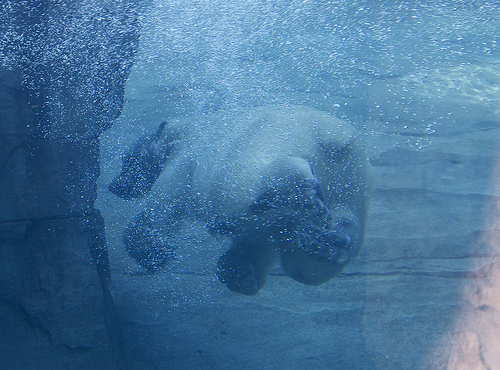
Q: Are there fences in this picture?
A: No, there are no fences.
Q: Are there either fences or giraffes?
A: No, there are no fences or giraffes.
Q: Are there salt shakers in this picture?
A: No, there are no salt shakers.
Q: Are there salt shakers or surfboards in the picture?
A: No, there are no salt shakers or surfboards.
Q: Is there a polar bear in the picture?
A: Yes, there is a polar bear.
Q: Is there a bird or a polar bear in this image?
A: Yes, there is a polar bear.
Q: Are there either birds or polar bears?
A: Yes, there is a polar bear.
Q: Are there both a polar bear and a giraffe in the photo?
A: No, there is a polar bear but no giraffes.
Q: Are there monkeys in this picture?
A: No, there are no monkeys.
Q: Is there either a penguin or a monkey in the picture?
A: No, there are no monkeys or penguins.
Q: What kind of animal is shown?
A: The animal is a polar bear.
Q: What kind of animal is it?
A: The animal is a polar bear.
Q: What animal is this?
A: That is a polar bear.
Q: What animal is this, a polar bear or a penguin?
A: That is a polar bear.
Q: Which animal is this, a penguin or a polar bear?
A: That is a polar bear.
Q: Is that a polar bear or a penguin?
A: That is a polar bear.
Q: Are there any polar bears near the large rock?
A: Yes, there is a polar bear near the rock.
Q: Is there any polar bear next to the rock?
A: Yes, there is a polar bear next to the rock.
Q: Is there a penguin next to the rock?
A: No, there is a polar bear next to the rock.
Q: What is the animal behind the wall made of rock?
A: The animal is a polar bear.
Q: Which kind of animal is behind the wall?
A: The animal is a polar bear.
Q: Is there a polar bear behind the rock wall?
A: Yes, there is a polar bear behind the wall.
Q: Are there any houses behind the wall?
A: No, there is a polar bear behind the wall.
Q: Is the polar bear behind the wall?
A: Yes, the polar bear is behind the wall.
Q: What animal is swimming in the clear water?
A: The polar bear is swimming in the water.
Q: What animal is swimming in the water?
A: The polar bear is swimming in the water.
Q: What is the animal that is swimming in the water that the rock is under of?
A: The animal is a polar bear.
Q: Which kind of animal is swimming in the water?
A: The animal is a polar bear.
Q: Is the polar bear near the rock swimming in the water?
A: Yes, the polar bear is swimming in the water.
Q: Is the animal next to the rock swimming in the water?
A: Yes, the polar bear is swimming in the water.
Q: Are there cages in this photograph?
A: No, there are no cages.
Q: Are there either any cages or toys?
A: No, there are no cages or toys.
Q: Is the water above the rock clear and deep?
A: Yes, the water is clear and deep.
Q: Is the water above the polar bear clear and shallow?
A: No, the water is clear but deep.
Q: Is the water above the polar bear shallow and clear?
A: No, the water is clear but deep.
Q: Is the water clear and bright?
A: Yes, the water is clear and bright.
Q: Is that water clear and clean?
A: Yes, the water is clear and clean.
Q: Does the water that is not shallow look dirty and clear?
A: No, the water is clear but clean.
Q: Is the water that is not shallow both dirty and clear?
A: No, the water is clear but clean.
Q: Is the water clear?
A: Yes, the water is clear.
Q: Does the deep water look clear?
A: Yes, the water is clear.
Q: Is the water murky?
A: No, the water is clear.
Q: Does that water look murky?
A: No, the water is clear.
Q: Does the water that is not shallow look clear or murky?
A: The water is clear.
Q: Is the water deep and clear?
A: Yes, the water is deep and clear.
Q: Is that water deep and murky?
A: No, the water is deep but clear.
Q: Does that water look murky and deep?
A: No, the water is deep but clear.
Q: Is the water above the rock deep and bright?
A: Yes, the water is deep and bright.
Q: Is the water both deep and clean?
A: Yes, the water is deep and clean.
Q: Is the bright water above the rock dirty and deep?
A: No, the water is deep but clean.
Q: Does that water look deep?
A: Yes, the water is deep.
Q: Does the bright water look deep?
A: Yes, the water is deep.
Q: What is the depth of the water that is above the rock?
A: The water is deep.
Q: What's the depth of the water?
A: The water is deep.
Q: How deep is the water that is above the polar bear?
A: The water is deep.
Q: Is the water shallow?
A: No, the water is deep.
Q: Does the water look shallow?
A: No, the water is deep.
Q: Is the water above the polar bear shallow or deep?
A: The water is deep.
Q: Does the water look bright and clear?
A: Yes, the water is bright and clear.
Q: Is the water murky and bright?
A: No, the water is bright but clear.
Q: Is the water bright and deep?
A: Yes, the water is bright and deep.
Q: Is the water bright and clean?
A: Yes, the water is bright and clean.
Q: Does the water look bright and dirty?
A: No, the water is bright but clean.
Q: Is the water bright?
A: Yes, the water is bright.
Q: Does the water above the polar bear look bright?
A: Yes, the water is bright.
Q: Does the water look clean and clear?
A: Yes, the water is clean and clear.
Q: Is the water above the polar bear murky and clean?
A: No, the water is clean but clear.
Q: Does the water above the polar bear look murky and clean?
A: No, the water is clean but clear.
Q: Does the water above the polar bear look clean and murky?
A: No, the water is clean but clear.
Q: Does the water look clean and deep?
A: Yes, the water is clean and deep.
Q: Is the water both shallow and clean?
A: No, the water is clean but deep.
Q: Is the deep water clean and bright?
A: Yes, the water is clean and bright.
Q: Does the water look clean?
A: Yes, the water is clean.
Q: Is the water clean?
A: Yes, the water is clean.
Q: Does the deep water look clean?
A: Yes, the water is clean.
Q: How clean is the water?
A: The water is clean.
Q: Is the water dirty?
A: No, the water is clean.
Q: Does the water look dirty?
A: No, the water is clean.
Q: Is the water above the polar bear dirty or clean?
A: The water is clean.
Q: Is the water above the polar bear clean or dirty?
A: The water is clean.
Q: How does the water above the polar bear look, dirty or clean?
A: The water is clean.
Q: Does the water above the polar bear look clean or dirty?
A: The water is clean.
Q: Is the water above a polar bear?
A: Yes, the water is above a polar bear.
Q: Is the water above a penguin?
A: No, the water is above a polar bear.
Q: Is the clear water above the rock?
A: Yes, the water is above the rock.